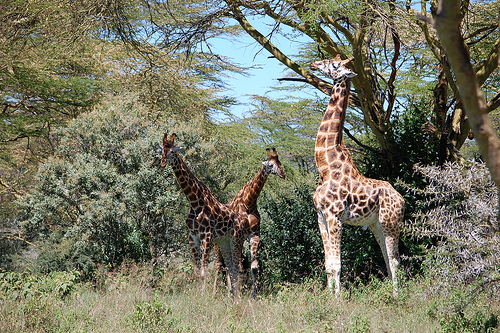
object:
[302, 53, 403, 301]
giraffe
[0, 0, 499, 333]
wild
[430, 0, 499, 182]
trunk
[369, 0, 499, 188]
tree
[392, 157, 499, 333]
vegetation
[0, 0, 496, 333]
picture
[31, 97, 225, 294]
shrubs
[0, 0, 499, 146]
skies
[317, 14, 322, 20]
leaves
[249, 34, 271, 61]
twigs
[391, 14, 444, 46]
nest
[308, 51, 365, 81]
head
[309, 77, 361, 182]
neck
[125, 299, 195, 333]
grass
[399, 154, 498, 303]
bush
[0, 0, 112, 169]
trees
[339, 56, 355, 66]
horns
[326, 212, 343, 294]
leg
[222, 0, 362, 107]
branches